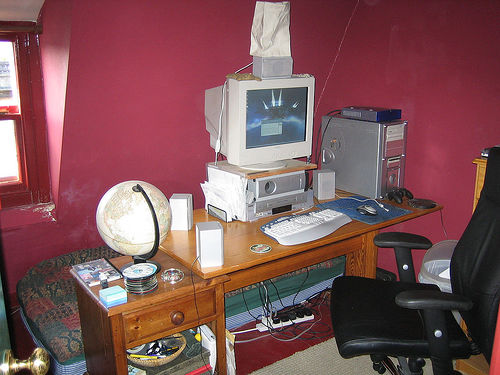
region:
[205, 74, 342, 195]
white monitor on desk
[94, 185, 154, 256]
white globe on desk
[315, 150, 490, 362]
black chair near desk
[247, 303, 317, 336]
white surge suppressor under desk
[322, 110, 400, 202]
grey tower on desk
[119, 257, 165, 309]
stack of CDs near globe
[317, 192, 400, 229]
blue mousepad on desk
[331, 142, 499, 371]
Black padded office chair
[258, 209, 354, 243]
Keyboard of a PC computer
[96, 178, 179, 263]
Globe of the world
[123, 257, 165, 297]
Stack of discs on a table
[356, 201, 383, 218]
Grey and black computer mouse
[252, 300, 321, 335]
Multi-plug connected with cords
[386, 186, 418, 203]
Control of a gaming system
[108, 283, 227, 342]
Drawer on a small table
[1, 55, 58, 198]
Window with a red frame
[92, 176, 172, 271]
globe on desk top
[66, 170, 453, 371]
brown wooden office desk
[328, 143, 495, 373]
black leather office chair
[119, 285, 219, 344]
side drawer on wooden desk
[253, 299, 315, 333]
white power strip on floor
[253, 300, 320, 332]
power strip under desk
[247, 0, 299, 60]
white bag atop monitor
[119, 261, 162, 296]
stack of silver discs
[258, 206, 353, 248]
computer keyboard on desk top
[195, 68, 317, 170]
computer monitor on desk top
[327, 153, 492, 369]
a black leather chair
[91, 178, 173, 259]
a globe of the world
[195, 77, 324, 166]
a gray computer monitor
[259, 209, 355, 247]
white and gray keyboard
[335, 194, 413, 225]
computer mouse on mouse pad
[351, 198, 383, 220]
a black and gray computer mouse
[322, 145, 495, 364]
black chair with arms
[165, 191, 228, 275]
two computer speakers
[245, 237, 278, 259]
CD on top of desk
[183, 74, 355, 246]
computer and keyboard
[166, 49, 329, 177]
a white computer screen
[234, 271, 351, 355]
a power strip under a computer desk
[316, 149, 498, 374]
a black computer chair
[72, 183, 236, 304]
a world globe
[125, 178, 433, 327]
a brown wooden computer desk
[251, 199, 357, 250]
a white keyboard on a desk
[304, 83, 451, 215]
a silver computer tower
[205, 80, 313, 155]
old large white monitor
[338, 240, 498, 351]
black swivel office chair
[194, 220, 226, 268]
white box shaped computer speaker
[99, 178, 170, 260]
white globe with black base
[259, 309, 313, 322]
power strip completely filled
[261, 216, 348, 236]
white and silver keyboard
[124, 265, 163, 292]
stack of CDs on desk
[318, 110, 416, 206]
small silver computer tower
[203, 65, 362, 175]
old cathode ray monitor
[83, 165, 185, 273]
white round world globe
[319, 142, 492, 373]
long backed black office chair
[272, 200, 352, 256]
white office keyboard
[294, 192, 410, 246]
large blue mousepad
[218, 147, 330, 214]
silver and white soundsystem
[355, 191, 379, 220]
small silver and black mouse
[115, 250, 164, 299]
stack of round dvds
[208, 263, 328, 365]
tangle of black and white cords